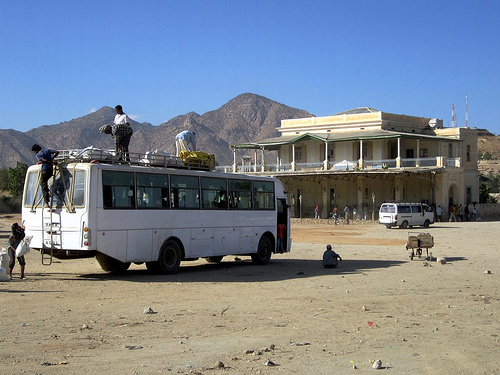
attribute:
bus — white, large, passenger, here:
[24, 162, 290, 272]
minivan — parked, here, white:
[378, 202, 435, 229]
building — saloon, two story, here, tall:
[216, 111, 481, 222]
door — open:
[276, 197, 286, 251]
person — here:
[315, 204, 322, 223]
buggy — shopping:
[406, 233, 434, 261]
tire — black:
[153, 242, 182, 274]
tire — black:
[253, 237, 273, 265]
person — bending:
[7, 222, 29, 281]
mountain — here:
[196, 94, 317, 148]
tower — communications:
[450, 101, 455, 127]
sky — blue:
[1, 1, 499, 135]